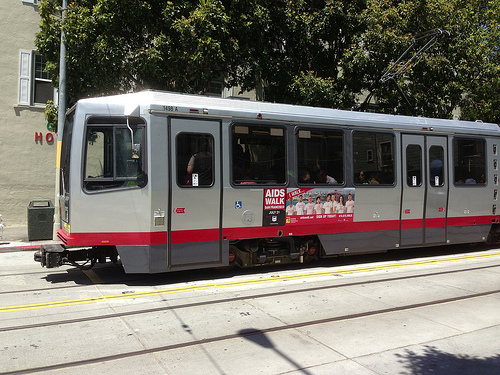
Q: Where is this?
A: This is at the pavement.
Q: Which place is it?
A: It is a pavement.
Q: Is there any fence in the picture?
A: No, there are no fences.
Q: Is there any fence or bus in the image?
A: No, there are no fences or buses.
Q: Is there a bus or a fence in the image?
A: No, there are no fences or buses.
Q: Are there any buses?
A: No, there are no buses.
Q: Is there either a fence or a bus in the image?
A: No, there are no buses or fences.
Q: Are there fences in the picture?
A: No, there are no fences.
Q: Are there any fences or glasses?
A: No, there are no fences or glasses.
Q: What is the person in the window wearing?
A: The person is wearing a shirt.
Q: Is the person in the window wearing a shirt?
A: Yes, the person is wearing a shirt.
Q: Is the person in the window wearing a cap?
A: No, the person is wearing a shirt.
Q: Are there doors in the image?
A: Yes, there is a door.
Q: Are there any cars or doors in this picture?
A: Yes, there is a door.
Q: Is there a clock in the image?
A: No, there are no clocks.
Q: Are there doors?
A: Yes, there is a door.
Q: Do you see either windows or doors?
A: Yes, there is a door.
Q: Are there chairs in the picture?
A: No, there are no chairs.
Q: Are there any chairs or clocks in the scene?
A: No, there are no chairs or clocks.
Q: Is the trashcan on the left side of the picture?
A: Yes, the trashcan is on the left of the image.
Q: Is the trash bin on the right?
A: No, the trash bin is on the left of the image.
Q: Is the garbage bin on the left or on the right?
A: The garbage bin is on the left of the image.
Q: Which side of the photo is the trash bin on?
A: The trash bin is on the left of the image.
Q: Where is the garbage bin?
A: The garbage bin is on the side walk.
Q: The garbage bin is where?
A: The garbage bin is on the side walk.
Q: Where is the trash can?
A: The garbage bin is on the side walk.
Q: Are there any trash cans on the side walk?
A: Yes, there is a trash can on the side walk.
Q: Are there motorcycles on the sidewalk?
A: No, there is a trash can on the sidewalk.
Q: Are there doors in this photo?
A: Yes, there is a door.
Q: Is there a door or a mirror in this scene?
A: Yes, there is a door.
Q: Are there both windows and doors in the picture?
A: Yes, there are both a door and windows.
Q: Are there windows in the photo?
A: Yes, there is a window.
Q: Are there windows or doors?
A: Yes, there is a window.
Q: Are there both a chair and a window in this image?
A: No, there is a window but no chairs.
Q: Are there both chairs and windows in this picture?
A: No, there is a window but no chairs.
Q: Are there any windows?
A: Yes, there is a window.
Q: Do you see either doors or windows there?
A: Yes, there is a window.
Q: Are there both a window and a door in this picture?
A: Yes, there are both a window and a door.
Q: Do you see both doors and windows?
A: Yes, there are both a window and a door.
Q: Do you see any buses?
A: No, there are no buses.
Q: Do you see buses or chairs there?
A: No, there are no buses or chairs.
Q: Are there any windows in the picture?
A: Yes, there is a window.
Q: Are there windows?
A: Yes, there is a window.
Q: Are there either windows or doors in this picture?
A: Yes, there is a window.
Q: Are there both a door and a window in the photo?
A: Yes, there are both a window and a door.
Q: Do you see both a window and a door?
A: Yes, there are both a window and a door.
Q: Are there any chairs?
A: No, there are no chairs.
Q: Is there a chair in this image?
A: No, there are no chairs.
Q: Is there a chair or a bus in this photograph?
A: No, there are no chairs or buses.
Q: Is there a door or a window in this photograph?
A: Yes, there is a window.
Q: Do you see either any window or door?
A: Yes, there is a window.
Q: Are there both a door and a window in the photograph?
A: Yes, there are both a window and a door.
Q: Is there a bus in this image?
A: No, there are no buses.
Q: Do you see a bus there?
A: No, there are no buses.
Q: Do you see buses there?
A: No, there are no buses.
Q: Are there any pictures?
A: No, there are no pictures.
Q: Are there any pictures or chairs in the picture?
A: No, there are no pictures or chairs.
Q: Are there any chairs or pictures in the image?
A: No, there are no pictures or chairs.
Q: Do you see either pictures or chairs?
A: No, there are no pictures or chairs.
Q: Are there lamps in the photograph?
A: No, there are no lamps.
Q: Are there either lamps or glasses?
A: No, there are no lamps or glasses.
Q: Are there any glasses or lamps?
A: No, there are no lamps or glasses.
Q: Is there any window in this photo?
A: Yes, there is a window.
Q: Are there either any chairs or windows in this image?
A: Yes, there is a window.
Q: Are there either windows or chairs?
A: Yes, there is a window.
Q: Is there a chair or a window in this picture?
A: Yes, there is a window.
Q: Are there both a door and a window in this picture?
A: Yes, there are both a window and a door.